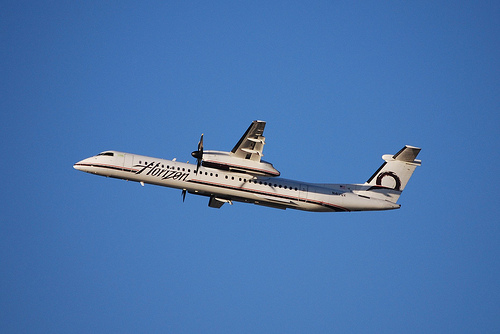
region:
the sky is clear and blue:
[9, 2, 496, 332]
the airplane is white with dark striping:
[72, 117, 424, 226]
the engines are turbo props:
[170, 130, 281, 223]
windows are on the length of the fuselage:
[133, 157, 305, 196]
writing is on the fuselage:
[132, 158, 189, 186]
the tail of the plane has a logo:
[363, 141, 423, 202]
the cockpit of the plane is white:
[71, 145, 127, 180]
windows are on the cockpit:
[93, 145, 115, 161]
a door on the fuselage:
[120, 146, 137, 174]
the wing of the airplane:
[228, 117, 266, 183]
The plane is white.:
[72, 124, 437, 229]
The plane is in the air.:
[48, 95, 435, 232]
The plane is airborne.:
[45, 98, 458, 241]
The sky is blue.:
[0, 2, 498, 332]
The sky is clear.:
[1, 2, 497, 332]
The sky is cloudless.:
[1, 2, 498, 332]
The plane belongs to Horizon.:
[71, 105, 428, 225]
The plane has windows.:
[136, 160, 312, 200]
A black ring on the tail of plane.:
[351, 128, 419, 216]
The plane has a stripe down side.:
[43, 87, 459, 219]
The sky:
[254, 253, 344, 327]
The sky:
[289, 291, 317, 329]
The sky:
[230, 220, 307, 314]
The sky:
[216, 234, 282, 304]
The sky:
[311, 267, 376, 325]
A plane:
[211, 106, 291, 225]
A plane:
[270, 99, 313, 204]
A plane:
[241, 81, 332, 287]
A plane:
[217, 123, 247, 218]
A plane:
[196, 44, 353, 310]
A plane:
[262, 153, 332, 296]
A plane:
[233, 31, 318, 210]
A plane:
[168, 40, 283, 308]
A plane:
[281, 99, 351, 218]